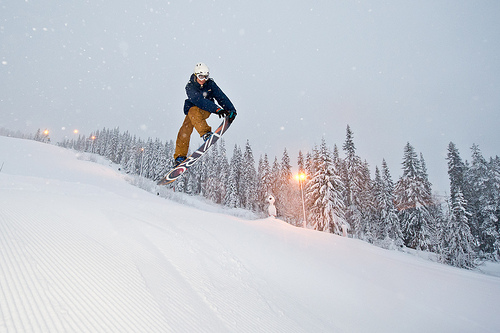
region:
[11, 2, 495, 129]
light in daytime sky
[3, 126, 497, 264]
line of trees on hill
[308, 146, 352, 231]
snow on tree branches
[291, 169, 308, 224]
glowing light on pole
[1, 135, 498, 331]
white snow on slope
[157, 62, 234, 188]
man on flying snowboard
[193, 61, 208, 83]
white helmet on head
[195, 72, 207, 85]
white goggles on face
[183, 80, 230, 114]
blue coat on body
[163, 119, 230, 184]
design on bottom of snowboard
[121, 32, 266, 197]
person in the air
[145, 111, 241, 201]
snowboard on the ground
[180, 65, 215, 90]
head of the person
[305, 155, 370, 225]
snow on the trees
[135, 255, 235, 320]
snow on the ground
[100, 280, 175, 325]
tracks in the snow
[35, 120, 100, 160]
trees in the distance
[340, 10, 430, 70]
sky above the trees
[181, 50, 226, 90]
white helmet on person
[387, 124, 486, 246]
Snow covered pine trees.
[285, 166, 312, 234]
Bright light on the slope.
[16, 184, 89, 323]
Tracks in the snow made by the groomers.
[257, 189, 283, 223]
A snowman stands watch.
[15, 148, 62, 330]
A long snow covered hill.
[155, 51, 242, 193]
Person is using a snowboard.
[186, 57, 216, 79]
Boarder wears a white hat.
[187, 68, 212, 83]
Boarder is wearing goggles.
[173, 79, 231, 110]
The person is wearing a blue jacket.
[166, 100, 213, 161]
Boarder wearing brown pants.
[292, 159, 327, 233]
the light is on the pole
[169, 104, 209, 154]
the pants are brown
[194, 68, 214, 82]
the goggles are white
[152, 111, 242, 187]
the board is black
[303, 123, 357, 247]
the tree is covered in snow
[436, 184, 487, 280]
the tree is small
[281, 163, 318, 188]
the lights are yellow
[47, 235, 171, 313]
the snow is tightly packed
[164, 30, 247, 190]
the person is snowboarding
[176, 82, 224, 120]
the jacket is blue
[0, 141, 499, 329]
the snow is sloppy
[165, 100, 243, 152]
the pants are orange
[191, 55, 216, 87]
the helmet is white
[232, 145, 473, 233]
snow is on the trees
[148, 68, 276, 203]
the man is in the air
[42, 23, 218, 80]
snow is in the air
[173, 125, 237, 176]
the surfboard has graphics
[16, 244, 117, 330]
lines are in the snow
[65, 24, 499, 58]
the sky has no clouds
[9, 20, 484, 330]
the season is winter